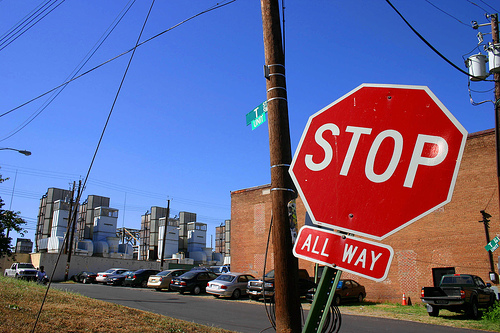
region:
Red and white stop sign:
[277, 77, 434, 277]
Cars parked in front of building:
[97, 260, 290, 306]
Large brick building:
[225, 173, 496, 246]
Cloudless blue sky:
[73, 85, 223, 156]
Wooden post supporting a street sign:
[242, 83, 314, 328]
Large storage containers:
[35, 170, 230, 258]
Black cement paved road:
[90, 285, 236, 327]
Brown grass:
[12, 283, 84, 324]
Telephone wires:
[7, 70, 127, 141]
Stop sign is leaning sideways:
[299, 88, 423, 296]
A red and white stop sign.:
[295, 60, 457, 227]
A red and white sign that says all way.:
[288, 205, 399, 285]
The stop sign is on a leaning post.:
[286, 257, 353, 330]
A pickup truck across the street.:
[413, 250, 493, 316]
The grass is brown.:
[52, 303, 117, 329]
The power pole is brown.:
[240, 0, 305, 331]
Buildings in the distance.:
[20, 168, 231, 263]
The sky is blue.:
[155, 45, 230, 120]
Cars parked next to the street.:
[80, 251, 256, 296]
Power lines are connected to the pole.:
[5, 9, 158, 149]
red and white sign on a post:
[287, 72, 475, 287]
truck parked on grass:
[418, 270, 498, 327]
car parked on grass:
[203, 265, 260, 303]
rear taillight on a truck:
[456, 284, 470, 303]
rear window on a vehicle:
[212, 271, 238, 284]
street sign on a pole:
[242, 94, 279, 133]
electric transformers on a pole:
[452, 32, 498, 87]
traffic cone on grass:
[396, 288, 411, 312]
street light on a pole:
[13, 144, 35, 162]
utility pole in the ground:
[156, 196, 173, 276]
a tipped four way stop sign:
[279, 58, 470, 331]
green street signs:
[229, 83, 271, 143]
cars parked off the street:
[86, 256, 289, 299]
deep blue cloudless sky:
[3, 0, 433, 85]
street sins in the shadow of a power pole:
[474, 194, 498, 287]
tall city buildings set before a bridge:
[26, 183, 221, 269]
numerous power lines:
[4, 3, 259, 82]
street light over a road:
[2, 124, 44, 176]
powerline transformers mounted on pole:
[441, 48, 498, 88]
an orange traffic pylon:
[383, 285, 420, 310]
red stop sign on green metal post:
[293, 82, 468, 331]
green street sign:
[245, 99, 274, 131]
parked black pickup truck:
[416, 271, 498, 318]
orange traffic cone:
[399, 291, 411, 306]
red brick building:
[230, 126, 498, 306]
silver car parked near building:
[207, 268, 255, 301]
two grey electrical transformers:
[465, 41, 498, 79]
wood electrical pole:
[257, 0, 304, 331]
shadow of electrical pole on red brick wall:
[477, 206, 494, 271]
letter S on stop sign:
[303, 123, 343, 173]